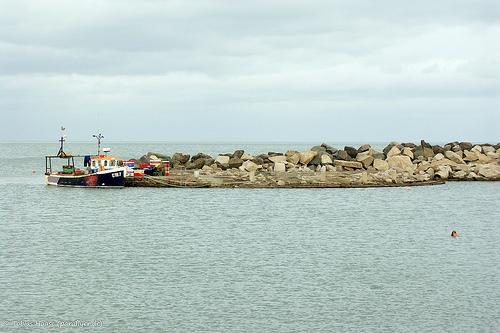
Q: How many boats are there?
A: One.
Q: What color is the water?
A: Blue.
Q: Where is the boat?
A: In the water.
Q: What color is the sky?
A: Gray.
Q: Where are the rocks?
A: To the right of the boat.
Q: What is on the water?
A: The boat.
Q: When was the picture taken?
A: Daytime.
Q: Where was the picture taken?
A: In a cove.